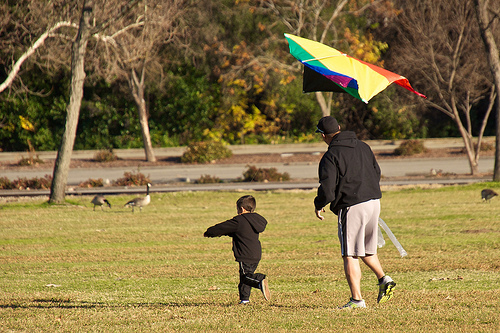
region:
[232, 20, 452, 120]
The kite is in the air.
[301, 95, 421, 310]
A man is walking on the grass.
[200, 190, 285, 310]
A little boy is running.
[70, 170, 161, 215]
Two Canadian geese are in the distance.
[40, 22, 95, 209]
The trunk of a tree.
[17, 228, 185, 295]
The grass is greenish brown.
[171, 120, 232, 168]
A small bush in the distance.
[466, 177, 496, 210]
Another bird in the background.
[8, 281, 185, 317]
A shadow on the grass.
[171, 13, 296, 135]
Green trees in the distance.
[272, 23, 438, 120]
A kite in the air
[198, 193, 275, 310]
a young boy running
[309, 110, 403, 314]
a man in a black hoodie walking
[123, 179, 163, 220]
a goose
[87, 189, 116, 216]
a goose with its head down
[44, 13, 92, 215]
the trunk of a tree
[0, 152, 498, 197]
a street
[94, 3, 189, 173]
a tree with no leaves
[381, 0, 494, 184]
a tree with no leaves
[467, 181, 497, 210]
a bird on the ground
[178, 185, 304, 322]
a small boy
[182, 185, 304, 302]
a small boy wearing a black sweatshirt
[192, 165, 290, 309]
a small boy wearing black pants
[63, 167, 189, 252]
two geese on the grass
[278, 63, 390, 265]
a man wearing a black hat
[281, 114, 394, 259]
a man wearing a hat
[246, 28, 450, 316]
a man flying a kite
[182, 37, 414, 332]
a small boy flying a kite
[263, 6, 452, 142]
a multi colored kite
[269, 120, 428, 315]
a man wearing a black sweatshirt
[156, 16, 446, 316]
The two people are flying a kite.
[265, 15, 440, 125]
A multicolored kite.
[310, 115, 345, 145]
The man is wearing a hat.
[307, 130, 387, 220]
The man is wearing a hoodie.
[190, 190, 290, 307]
The boy is running.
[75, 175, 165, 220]
Two large birds.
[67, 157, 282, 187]
Small bushes.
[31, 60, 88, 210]
A tree trunk.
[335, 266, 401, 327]
The man is wearing sneakers.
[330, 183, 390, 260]
The man is wearing gray shorts.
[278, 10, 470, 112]
a colorful kite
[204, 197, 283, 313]
little boy running on the grass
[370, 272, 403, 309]
yellow and black sole of a shoe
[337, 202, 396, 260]
man wearing gray shorts with black lines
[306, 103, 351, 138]
man wearing a black cap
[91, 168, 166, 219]
two birds on the grass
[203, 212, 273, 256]
boy wearing a black hoodie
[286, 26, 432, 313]
a man flying a kite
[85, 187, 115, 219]
a bird pecking the ground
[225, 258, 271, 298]
black pants with a white line